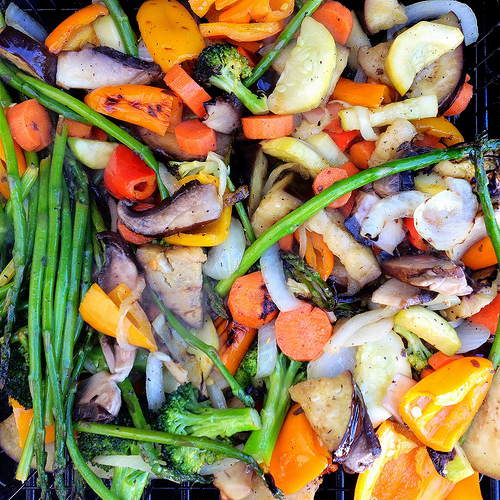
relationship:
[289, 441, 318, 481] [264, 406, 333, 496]
edge of fruit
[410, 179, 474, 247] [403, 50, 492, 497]
food on side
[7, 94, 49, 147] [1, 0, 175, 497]
food on side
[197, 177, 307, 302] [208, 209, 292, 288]
middle has food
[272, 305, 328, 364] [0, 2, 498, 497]
carrot in mix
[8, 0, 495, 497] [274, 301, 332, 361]
stir fry has carrot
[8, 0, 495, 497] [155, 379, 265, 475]
stir fry has vegetable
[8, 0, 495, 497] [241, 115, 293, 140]
stir fry has carrot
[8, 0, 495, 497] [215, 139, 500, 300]
stir fry has food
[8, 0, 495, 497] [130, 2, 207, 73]
stir fry has vegetable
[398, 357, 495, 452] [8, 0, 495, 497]
pepper in stir fry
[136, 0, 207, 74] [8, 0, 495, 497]
vegetable in stir fry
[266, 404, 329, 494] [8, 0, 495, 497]
peppers in stir fry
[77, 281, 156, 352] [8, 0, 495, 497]
food in stir fry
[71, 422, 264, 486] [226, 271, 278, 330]
bean in carrot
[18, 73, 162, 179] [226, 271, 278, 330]
bean in carrot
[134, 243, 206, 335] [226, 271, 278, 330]
meat in carrot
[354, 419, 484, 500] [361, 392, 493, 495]
vegetables in corner